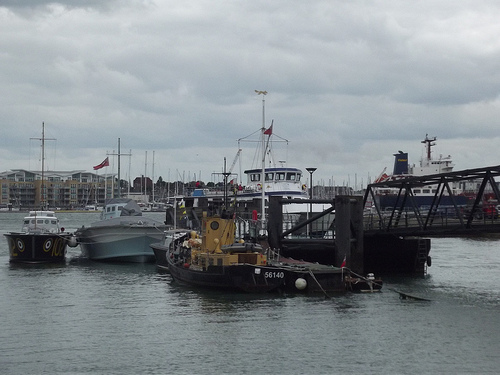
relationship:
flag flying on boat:
[91, 151, 113, 171] [62, 120, 174, 270]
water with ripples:
[0, 213, 499, 373] [62, 279, 187, 359]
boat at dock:
[163, 186, 348, 293] [171, 193, 431, 278]